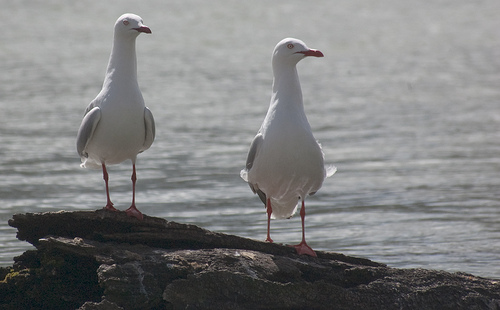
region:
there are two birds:
[58, 7, 376, 278]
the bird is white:
[211, 6, 344, 238]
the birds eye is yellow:
[281, 40, 297, 55]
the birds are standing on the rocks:
[47, 186, 333, 275]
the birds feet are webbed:
[237, 230, 334, 261]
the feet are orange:
[225, 215, 335, 266]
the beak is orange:
[297, 45, 339, 65]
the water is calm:
[340, 41, 478, 257]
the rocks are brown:
[40, 195, 289, 304]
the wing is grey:
[60, 87, 107, 165]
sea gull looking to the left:
[72, 7, 156, 231]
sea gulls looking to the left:
[61, 7, 368, 280]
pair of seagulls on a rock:
[66, 9, 343, 264]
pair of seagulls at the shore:
[56, 5, 350, 267]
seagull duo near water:
[30, 9, 373, 289]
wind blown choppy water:
[349, 29, 484, 257]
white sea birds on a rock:
[69, 4, 336, 270]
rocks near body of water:
[11, 209, 401, 308]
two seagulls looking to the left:
[63, 7, 377, 274]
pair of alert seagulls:
[54, 7, 364, 259]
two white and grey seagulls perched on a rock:
[65, 10, 375, 281]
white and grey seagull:
[236, 13, 352, 270]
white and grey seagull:
[69, 7, 198, 232]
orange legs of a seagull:
[94, 139, 162, 230]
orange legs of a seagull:
[250, 165, 332, 273]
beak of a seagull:
[129, 17, 161, 47]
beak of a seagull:
[292, 32, 330, 67]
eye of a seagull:
[119, 15, 131, 30]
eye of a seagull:
[284, 35, 296, 51]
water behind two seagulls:
[96, 9, 341, 130]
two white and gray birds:
[75, 10, 325, 260]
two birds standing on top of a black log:
[75, 11, 325, 253]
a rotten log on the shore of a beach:
[0, 205, 496, 305]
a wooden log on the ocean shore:
[0, 205, 495, 305]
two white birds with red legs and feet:
[75, 10, 336, 255]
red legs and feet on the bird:
[90, 160, 145, 215]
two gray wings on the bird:
[70, 105, 155, 155]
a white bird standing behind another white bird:
[71, 10, 153, 210]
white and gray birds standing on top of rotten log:
[5, 1, 495, 301]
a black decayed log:
[0, 205, 496, 305]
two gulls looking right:
[71, 10, 338, 262]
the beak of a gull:
[298, 42, 325, 61]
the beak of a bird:
[304, 40, 329, 64]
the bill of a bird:
[302, 46, 330, 61]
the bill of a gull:
[305, 38, 330, 63]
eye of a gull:
[281, 39, 300, 58]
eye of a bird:
[281, 38, 290, 56]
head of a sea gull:
[259, 24, 331, 82]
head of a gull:
[262, 25, 327, 98]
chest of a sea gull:
[225, 122, 328, 191]